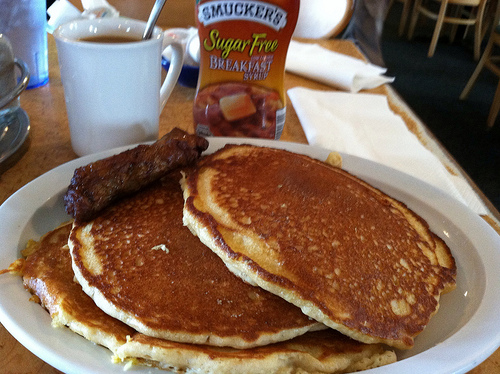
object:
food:
[7, 120, 465, 374]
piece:
[53, 123, 212, 228]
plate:
[0, 127, 497, 374]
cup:
[50, 14, 187, 161]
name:
[192, 1, 289, 35]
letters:
[196, 27, 290, 62]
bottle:
[183, 0, 311, 150]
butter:
[216, 87, 261, 124]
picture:
[187, 75, 292, 146]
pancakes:
[173, 139, 463, 354]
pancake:
[12, 211, 403, 374]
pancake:
[61, 155, 329, 353]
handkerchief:
[284, 84, 492, 229]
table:
[0, 0, 497, 373]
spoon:
[139, 0, 167, 42]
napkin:
[279, 37, 398, 98]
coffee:
[79, 33, 143, 41]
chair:
[449, 0, 500, 134]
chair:
[393, 1, 489, 64]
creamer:
[158, 25, 193, 118]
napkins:
[283, 37, 403, 96]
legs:
[417, 0, 455, 63]